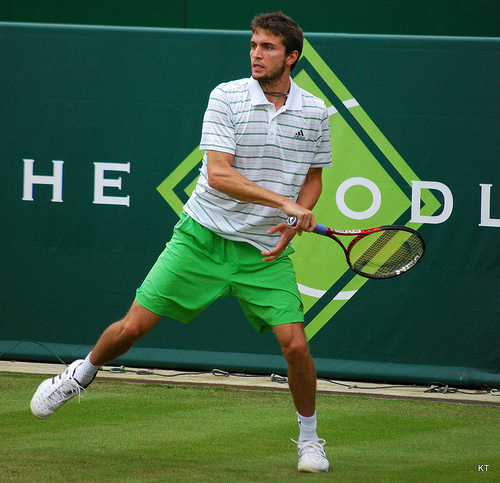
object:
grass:
[0, 284, 499, 409]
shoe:
[30, 360, 92, 418]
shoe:
[290, 435, 330, 475]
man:
[28, 13, 331, 473]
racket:
[285, 217, 426, 280]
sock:
[71, 353, 98, 386]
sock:
[293, 410, 320, 443]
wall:
[0, 19, 499, 383]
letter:
[21, 156, 65, 205]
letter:
[92, 162, 130, 205]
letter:
[333, 176, 382, 219]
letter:
[409, 179, 455, 223]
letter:
[478, 182, 500, 228]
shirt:
[184, 78, 333, 255]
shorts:
[137, 208, 307, 335]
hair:
[251, 11, 303, 54]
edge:
[2, 19, 498, 46]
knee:
[284, 341, 313, 358]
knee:
[120, 319, 141, 341]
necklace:
[261, 89, 287, 99]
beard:
[253, 53, 289, 83]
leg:
[88, 239, 210, 367]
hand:
[281, 200, 315, 235]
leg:
[271, 322, 319, 422]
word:
[20, 160, 500, 227]